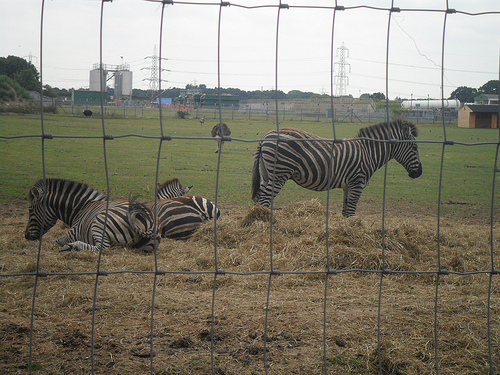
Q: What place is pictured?
A: It is a zoo.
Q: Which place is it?
A: It is a zoo.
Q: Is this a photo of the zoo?
A: Yes, it is showing the zoo.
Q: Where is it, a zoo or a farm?
A: It is a zoo.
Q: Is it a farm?
A: No, it is a zoo.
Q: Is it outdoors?
A: Yes, it is outdoors.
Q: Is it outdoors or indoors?
A: It is outdoors.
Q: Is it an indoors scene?
A: No, it is outdoors.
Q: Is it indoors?
A: No, it is outdoors.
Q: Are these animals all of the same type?
A: Yes, all the animals are zebras.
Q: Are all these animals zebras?
A: Yes, all the animals are zebras.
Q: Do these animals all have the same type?
A: Yes, all the animals are zebras.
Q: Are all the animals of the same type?
A: Yes, all the animals are zebras.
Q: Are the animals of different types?
A: No, all the animals are zebras.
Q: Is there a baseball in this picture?
A: No, there are no baseballs.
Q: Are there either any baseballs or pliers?
A: No, there are no baseballs or pliers.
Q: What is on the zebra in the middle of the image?
A: The hay is on the zebra.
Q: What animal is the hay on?
A: The hay is on the zebra.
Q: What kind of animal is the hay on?
A: The hay is on the zebra.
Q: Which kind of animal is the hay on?
A: The hay is on the zebra.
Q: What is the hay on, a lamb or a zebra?
A: The hay is on a zebra.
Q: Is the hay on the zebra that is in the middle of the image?
A: Yes, the hay is on the zebra.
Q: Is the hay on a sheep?
A: No, the hay is on the zebra.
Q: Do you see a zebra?
A: Yes, there is a zebra.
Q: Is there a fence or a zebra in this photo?
A: Yes, there is a zebra.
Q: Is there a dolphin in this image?
A: No, there are no dolphins.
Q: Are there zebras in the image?
A: Yes, there is a zebra.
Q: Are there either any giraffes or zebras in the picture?
A: Yes, there is a zebra.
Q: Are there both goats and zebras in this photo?
A: No, there is a zebra but no goats.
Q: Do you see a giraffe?
A: No, there are no giraffes.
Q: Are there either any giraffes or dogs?
A: No, there are no giraffes or dogs.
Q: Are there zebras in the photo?
A: Yes, there is a zebra.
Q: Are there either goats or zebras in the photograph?
A: Yes, there is a zebra.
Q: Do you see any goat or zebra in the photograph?
A: Yes, there is a zebra.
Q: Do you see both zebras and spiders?
A: No, there is a zebra but no spiders.